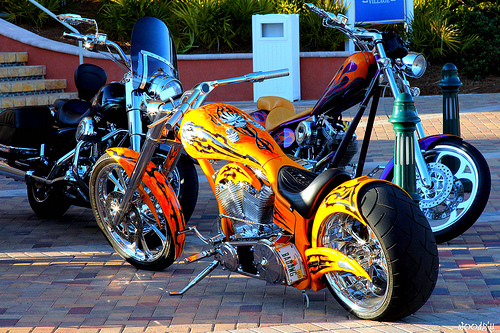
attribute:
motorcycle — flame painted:
[93, 66, 440, 329]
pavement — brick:
[6, 101, 498, 331]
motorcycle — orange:
[88, 55, 426, 318]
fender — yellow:
[310, 172, 380, 246]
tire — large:
[302, 181, 443, 321]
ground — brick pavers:
[1, 88, 495, 328]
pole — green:
[432, 70, 470, 135]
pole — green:
[384, 90, 429, 199]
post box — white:
[251, 54, 273, 89]